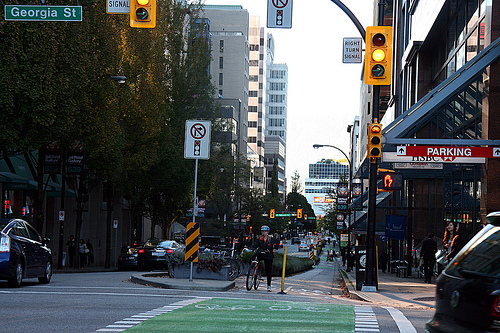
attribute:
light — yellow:
[130, 1, 159, 15]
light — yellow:
[367, 45, 392, 64]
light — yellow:
[369, 122, 384, 142]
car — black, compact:
[431, 210, 500, 333]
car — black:
[2, 212, 28, 278]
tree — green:
[85, 29, 182, 193]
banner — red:
[396, 143, 500, 164]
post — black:
[368, 166, 381, 284]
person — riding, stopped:
[257, 223, 277, 286]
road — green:
[139, 297, 365, 333]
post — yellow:
[281, 247, 291, 294]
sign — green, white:
[4, 3, 85, 25]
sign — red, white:
[396, 144, 499, 160]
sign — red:
[182, 119, 212, 161]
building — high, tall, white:
[198, 5, 252, 208]